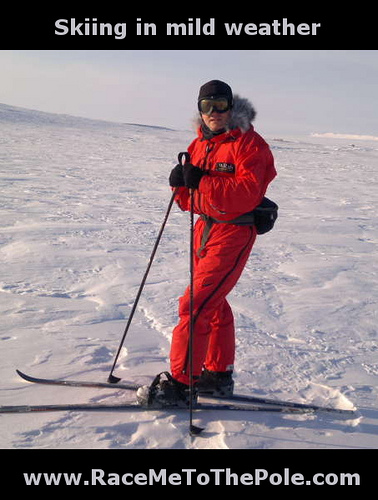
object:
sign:
[44, 4, 333, 49]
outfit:
[169, 123, 275, 380]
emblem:
[216, 161, 235, 173]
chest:
[184, 140, 233, 189]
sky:
[2, 44, 378, 132]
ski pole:
[184, 178, 205, 434]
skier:
[136, 79, 278, 405]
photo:
[0, 51, 375, 448]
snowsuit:
[169, 95, 277, 386]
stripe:
[217, 238, 252, 287]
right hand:
[168, 162, 185, 191]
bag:
[247, 194, 280, 235]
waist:
[197, 210, 259, 227]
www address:
[14, 466, 364, 493]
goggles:
[197, 99, 232, 114]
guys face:
[197, 95, 231, 131]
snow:
[1, 108, 375, 447]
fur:
[233, 93, 256, 128]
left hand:
[175, 155, 202, 190]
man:
[137, 78, 278, 411]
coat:
[170, 121, 277, 219]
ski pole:
[108, 186, 179, 381]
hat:
[197, 78, 236, 104]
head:
[196, 78, 234, 131]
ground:
[0, 132, 377, 451]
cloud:
[0, 45, 377, 115]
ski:
[15, 362, 361, 413]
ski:
[1, 402, 323, 415]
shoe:
[192, 368, 236, 400]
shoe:
[136, 369, 197, 406]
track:
[237, 272, 377, 397]